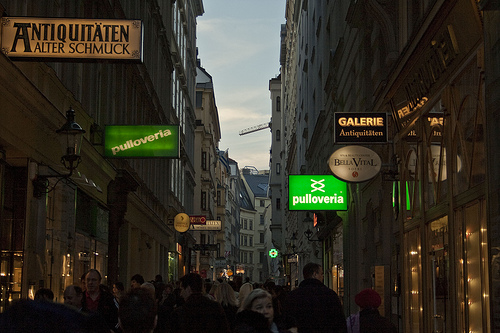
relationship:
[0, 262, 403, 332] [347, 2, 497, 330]
people in front of building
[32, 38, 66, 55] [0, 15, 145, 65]
word alter on lit up sign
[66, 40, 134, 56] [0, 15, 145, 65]
word schmuck on lit up sign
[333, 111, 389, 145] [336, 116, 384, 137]
black sign with lettering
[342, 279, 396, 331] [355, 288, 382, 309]
woman wearing cap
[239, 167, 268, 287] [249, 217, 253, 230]
buildings has windows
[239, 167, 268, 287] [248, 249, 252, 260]
buildings has windows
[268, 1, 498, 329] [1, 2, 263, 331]
buildings across from buildings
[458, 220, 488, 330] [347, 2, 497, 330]
lights on building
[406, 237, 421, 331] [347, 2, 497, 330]
lights on building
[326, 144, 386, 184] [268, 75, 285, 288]
sign hanging on buildings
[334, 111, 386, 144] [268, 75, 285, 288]
black sign hanging on buildings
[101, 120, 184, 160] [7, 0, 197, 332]
sign hanging on building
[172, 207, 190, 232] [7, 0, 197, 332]
sign hanging on building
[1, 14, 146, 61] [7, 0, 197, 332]
sign hanging on building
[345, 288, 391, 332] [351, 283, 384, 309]
woman wearing cap